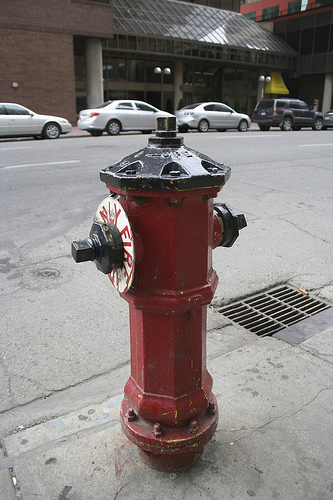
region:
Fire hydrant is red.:
[68, 123, 249, 475]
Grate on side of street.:
[216, 271, 332, 348]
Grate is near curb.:
[209, 275, 331, 354]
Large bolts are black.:
[48, 99, 257, 276]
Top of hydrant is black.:
[63, 103, 263, 474]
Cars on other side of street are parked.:
[0, 93, 332, 145]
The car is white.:
[0, 100, 76, 142]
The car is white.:
[74, 95, 176, 136]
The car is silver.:
[177, 96, 254, 137]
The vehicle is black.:
[253, 92, 327, 135]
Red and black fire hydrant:
[79, 101, 249, 478]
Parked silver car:
[67, 93, 173, 139]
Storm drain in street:
[199, 263, 327, 348]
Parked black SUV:
[252, 87, 328, 146]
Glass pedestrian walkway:
[60, 0, 298, 77]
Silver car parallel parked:
[170, 93, 251, 130]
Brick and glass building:
[0, 0, 317, 121]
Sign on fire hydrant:
[72, 190, 138, 294]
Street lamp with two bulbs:
[149, 59, 172, 118]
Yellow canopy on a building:
[259, 65, 289, 98]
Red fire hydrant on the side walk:
[79, 110, 265, 455]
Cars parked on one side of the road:
[0, 86, 322, 138]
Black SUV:
[249, 90, 330, 137]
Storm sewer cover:
[210, 283, 317, 346]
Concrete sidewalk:
[218, 337, 305, 465]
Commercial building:
[4, 1, 331, 112]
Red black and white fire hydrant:
[56, 99, 243, 468]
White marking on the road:
[3, 146, 91, 172]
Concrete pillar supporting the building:
[64, 18, 128, 114]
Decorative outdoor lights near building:
[117, 45, 290, 113]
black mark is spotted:
[245, 482, 256, 495]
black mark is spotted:
[242, 486, 251, 499]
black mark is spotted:
[241, 484, 248, 497]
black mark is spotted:
[244, 492, 255, 498]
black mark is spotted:
[247, 489, 250, 493]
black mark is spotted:
[247, 487, 255, 498]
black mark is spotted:
[246, 491, 250, 498]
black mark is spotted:
[246, 481, 252, 494]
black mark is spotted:
[242, 488, 254, 493]